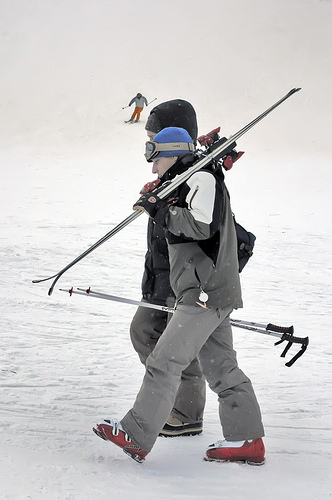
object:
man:
[92, 126, 268, 470]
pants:
[120, 302, 266, 455]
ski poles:
[57, 283, 294, 336]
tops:
[59, 286, 74, 296]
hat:
[151, 126, 194, 159]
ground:
[0, 3, 331, 500]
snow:
[3, 4, 330, 499]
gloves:
[133, 191, 166, 220]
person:
[128, 92, 148, 123]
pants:
[131, 107, 143, 120]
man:
[128, 99, 257, 440]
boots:
[158, 410, 203, 438]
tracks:
[0, 242, 332, 499]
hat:
[145, 98, 199, 146]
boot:
[203, 436, 267, 468]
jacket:
[164, 168, 244, 311]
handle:
[274, 333, 309, 368]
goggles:
[143, 140, 195, 163]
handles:
[265, 322, 294, 335]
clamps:
[111, 419, 119, 437]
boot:
[92, 417, 151, 466]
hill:
[3, 4, 331, 211]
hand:
[132, 190, 166, 220]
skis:
[130, 119, 142, 125]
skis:
[31, 86, 303, 285]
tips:
[32, 274, 58, 284]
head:
[144, 126, 195, 180]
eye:
[155, 157, 160, 164]